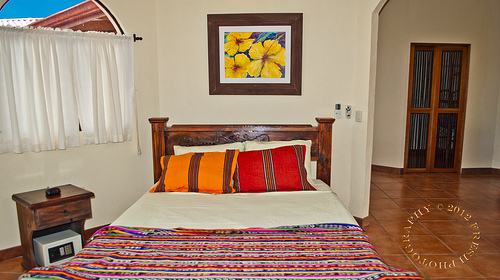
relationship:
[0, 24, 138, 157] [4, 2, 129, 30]
curtain covering window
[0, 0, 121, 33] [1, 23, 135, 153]
window above curtains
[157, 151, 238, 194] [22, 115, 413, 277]
pillow on bed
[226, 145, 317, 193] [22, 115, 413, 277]
pillow on bed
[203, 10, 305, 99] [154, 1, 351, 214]
picture on wall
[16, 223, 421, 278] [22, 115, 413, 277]
blanket on bed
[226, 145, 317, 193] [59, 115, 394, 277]
pillow laying on a bed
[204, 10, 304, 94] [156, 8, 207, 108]
painting hanging on a wall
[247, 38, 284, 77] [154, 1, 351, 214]
flower on wall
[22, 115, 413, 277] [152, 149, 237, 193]
bed with pillow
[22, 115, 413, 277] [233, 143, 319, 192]
bed with pillow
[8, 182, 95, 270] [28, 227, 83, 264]
nightstand with safe